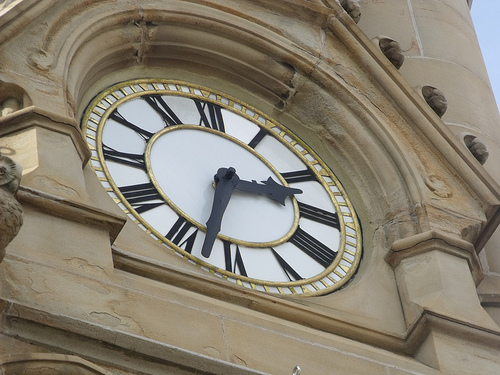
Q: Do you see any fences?
A: No, there are no fences.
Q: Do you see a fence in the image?
A: No, there are no fences.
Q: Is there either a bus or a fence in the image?
A: No, there are no fences or buses.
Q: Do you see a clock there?
A: Yes, there is a clock.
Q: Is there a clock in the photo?
A: Yes, there is a clock.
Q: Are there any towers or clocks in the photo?
A: Yes, there is a clock.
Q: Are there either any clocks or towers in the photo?
A: Yes, there is a clock.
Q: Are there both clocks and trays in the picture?
A: No, there is a clock but no trays.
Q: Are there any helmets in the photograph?
A: No, there are no helmets.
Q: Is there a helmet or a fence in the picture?
A: No, there are no helmets or fences.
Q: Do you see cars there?
A: No, there are no cars.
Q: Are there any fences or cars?
A: No, there are no cars or fences.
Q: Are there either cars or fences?
A: No, there are no cars or fences.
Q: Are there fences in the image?
A: No, there are no fences.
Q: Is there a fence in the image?
A: No, there are no fences.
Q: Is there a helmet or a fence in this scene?
A: No, there are no fences or helmets.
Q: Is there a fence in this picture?
A: No, there are no fences.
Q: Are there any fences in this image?
A: No, there are no fences.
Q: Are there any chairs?
A: No, there are no chairs.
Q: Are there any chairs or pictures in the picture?
A: No, there are no chairs or pictures.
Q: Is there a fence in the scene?
A: No, there are no fences.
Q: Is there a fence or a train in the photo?
A: No, there are no fences or trains.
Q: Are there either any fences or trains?
A: No, there are no fences or trains.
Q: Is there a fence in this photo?
A: No, there are no fences.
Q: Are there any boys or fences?
A: No, there are no fences or boys.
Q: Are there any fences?
A: No, there are no fences.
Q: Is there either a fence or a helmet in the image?
A: No, there are no fences or helmets.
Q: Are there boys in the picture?
A: No, there are no boys.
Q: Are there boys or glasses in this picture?
A: No, there are no boys or glasses.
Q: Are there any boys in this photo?
A: No, there are no boys.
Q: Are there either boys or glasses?
A: No, there are no boys or glasses.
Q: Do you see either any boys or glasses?
A: No, there are no boys or glasses.